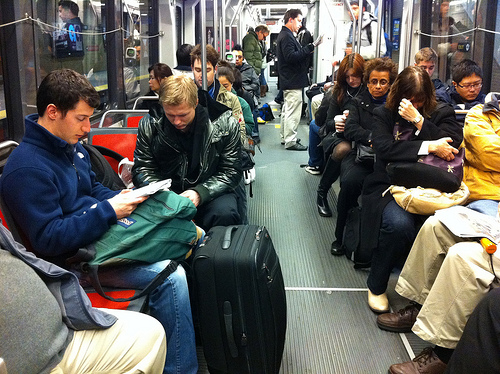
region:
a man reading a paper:
[11, 63, 172, 242]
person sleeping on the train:
[361, 59, 472, 170]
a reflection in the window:
[30, 4, 103, 69]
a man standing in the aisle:
[270, 5, 318, 155]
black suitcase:
[178, 207, 290, 371]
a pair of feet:
[365, 301, 448, 371]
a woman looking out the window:
[133, 55, 180, 114]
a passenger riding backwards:
[166, 34, 211, 80]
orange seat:
[80, 120, 152, 182]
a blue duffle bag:
[53, 175, 205, 290]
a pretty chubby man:
[1, 218, 166, 371]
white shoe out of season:
[365, 67, 467, 315]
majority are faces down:
[38, 44, 488, 188]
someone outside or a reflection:
[42, 0, 102, 70]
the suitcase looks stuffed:
[180, 218, 294, 370]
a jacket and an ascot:
[132, 74, 245, 226]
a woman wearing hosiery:
[309, 51, 375, 219]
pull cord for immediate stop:
[0, 8, 167, 61]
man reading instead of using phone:
[8, 68, 200, 371]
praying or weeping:
[370, 65, 465, 196]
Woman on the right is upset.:
[365, 69, 470, 314]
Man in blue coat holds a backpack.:
[0, 61, 202, 372]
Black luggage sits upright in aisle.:
[178, 210, 290, 371]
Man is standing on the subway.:
[268, 4, 325, 159]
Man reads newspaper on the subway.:
[273, 5, 329, 157]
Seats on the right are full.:
[308, 41, 498, 372]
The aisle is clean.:
[241, 25, 396, 372]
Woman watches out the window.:
[121, 16, 182, 121]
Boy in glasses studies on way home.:
[425, 53, 499, 133]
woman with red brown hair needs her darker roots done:
[330, 47, 369, 109]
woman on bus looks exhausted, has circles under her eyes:
[362, 56, 399, 101]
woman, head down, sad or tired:
[361, 64, 477, 314]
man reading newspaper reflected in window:
[34, 0, 94, 66]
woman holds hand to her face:
[381, 59, 441, 136]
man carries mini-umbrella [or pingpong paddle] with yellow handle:
[442, 203, 499, 280]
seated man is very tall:
[187, 40, 255, 156]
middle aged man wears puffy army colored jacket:
[238, 22, 275, 73]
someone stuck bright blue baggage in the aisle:
[255, 99, 277, 124]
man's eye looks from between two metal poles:
[343, 0, 366, 57]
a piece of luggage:
[197, 219, 302, 372]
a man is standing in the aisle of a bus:
[275, 5, 315, 151]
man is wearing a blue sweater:
[0, 115, 139, 260]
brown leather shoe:
[387, 339, 455, 373]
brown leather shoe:
[374, 299, 418, 332]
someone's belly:
[0, 247, 73, 372]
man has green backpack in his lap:
[78, 181, 208, 269]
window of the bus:
[20, 6, 106, 100]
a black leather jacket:
[127, 116, 246, 193]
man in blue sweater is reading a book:
[2, 65, 294, 367]